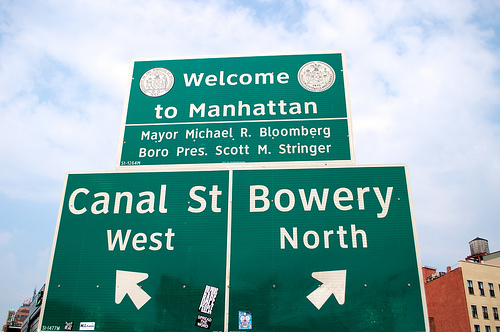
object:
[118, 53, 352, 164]
sign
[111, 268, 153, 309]
arrow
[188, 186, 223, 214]
street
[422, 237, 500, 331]
building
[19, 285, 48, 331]
train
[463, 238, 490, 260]
tower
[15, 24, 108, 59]
clouds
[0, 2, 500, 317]
sky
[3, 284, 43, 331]
buildings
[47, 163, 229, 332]
sign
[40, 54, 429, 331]
three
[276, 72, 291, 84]
letters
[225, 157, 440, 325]
sign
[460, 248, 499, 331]
tan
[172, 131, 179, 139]
letters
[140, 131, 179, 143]
mayor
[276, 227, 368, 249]
north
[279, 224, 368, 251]
lettering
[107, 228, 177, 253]
west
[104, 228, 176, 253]
lettering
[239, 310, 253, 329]
figure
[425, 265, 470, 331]
brick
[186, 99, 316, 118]
manhattan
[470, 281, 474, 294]
windows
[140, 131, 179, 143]
lettering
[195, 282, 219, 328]
black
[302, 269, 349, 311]
arrow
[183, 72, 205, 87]
letter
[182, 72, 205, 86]
w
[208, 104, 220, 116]
white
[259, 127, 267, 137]
white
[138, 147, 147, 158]
b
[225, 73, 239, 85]
white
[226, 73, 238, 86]
c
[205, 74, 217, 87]
e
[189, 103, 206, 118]
m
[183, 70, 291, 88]
welcome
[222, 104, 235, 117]
n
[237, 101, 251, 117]
h